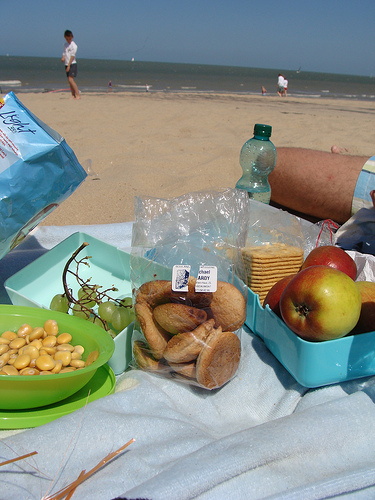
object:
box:
[228, 257, 375, 389]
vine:
[61, 242, 133, 332]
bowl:
[0, 304, 115, 410]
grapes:
[50, 242, 137, 339]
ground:
[0, 92, 374, 500]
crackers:
[240, 241, 303, 307]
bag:
[128, 187, 248, 391]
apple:
[279, 265, 362, 341]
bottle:
[235, 123, 277, 204]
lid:
[253, 124, 272, 137]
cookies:
[132, 276, 246, 390]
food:
[0, 91, 375, 430]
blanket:
[0, 221, 375, 500]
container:
[3, 231, 172, 376]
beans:
[0, 319, 99, 375]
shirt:
[62, 41, 78, 66]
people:
[276, 73, 288, 97]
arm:
[61, 42, 66, 63]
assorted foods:
[0, 231, 375, 430]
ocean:
[0, 55, 374, 101]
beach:
[0, 92, 375, 226]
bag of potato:
[0, 90, 88, 259]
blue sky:
[0, 1, 375, 78]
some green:
[312, 269, 375, 341]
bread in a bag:
[128, 187, 250, 276]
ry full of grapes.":
[50, 286, 135, 340]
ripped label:
[171, 265, 217, 293]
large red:
[262, 245, 358, 320]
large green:
[0, 284, 136, 430]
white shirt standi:
[112, 390, 375, 500]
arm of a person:
[61, 30, 81, 100]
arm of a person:
[252, 145, 375, 224]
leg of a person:
[68, 76, 81, 100]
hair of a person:
[64, 29, 74, 43]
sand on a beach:
[0, 90, 375, 227]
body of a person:
[61, 29, 81, 100]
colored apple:
[263, 246, 375, 340]